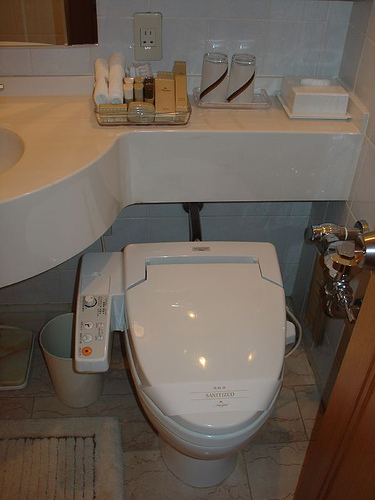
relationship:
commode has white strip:
[73, 237, 306, 486] [73, 253, 123, 374]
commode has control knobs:
[73, 237, 306, 486] [81, 291, 97, 310]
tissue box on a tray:
[282, 77, 348, 116] [274, 89, 351, 126]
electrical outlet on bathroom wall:
[129, 12, 164, 65] [1, 1, 373, 387]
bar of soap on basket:
[128, 99, 157, 127] [92, 86, 192, 126]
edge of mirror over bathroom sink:
[3, 1, 104, 52] [1, 94, 121, 290]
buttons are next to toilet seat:
[77, 294, 104, 357] [127, 262, 286, 435]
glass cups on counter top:
[201, 32, 255, 104] [1, 79, 368, 290]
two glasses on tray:
[201, 32, 255, 104] [189, 88, 273, 113]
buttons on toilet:
[77, 294, 104, 357] [73, 237, 306, 486]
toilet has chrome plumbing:
[73, 237, 306, 486] [178, 197, 209, 245]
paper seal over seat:
[141, 380, 279, 420] [127, 262, 286, 435]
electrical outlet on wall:
[129, 12, 164, 65] [1, 1, 373, 387]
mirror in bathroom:
[3, 1, 104, 52] [2, 0, 374, 495]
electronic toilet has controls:
[73, 237, 306, 486] [77, 294, 104, 357]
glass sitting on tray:
[227, 51, 256, 108] [191, 87, 274, 110]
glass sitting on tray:
[197, 49, 231, 105] [191, 87, 274, 110]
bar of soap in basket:
[128, 101, 156, 122] [93, 92, 190, 127]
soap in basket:
[95, 102, 127, 123] [93, 92, 190, 127]